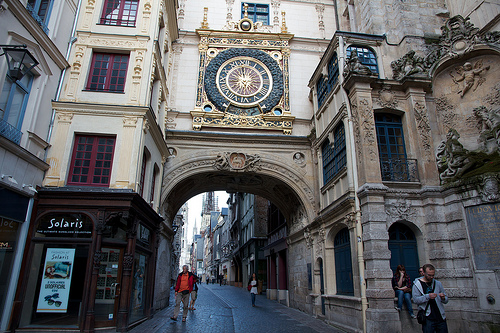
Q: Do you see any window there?
A: Yes, there is a window.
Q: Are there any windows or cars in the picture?
A: Yes, there is a window.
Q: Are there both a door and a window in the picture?
A: Yes, there are both a window and a door.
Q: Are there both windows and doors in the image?
A: Yes, there are both a window and a door.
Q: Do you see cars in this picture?
A: No, there are no cars.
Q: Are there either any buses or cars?
A: No, there are no cars or buses.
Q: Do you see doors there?
A: Yes, there is a door.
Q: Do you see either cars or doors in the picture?
A: Yes, there is a door.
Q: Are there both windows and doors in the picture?
A: Yes, there are both a door and a window.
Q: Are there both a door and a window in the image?
A: Yes, there are both a door and a window.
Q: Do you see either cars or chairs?
A: No, there are no cars or chairs.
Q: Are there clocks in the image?
A: Yes, there is a clock.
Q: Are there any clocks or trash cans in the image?
A: Yes, there is a clock.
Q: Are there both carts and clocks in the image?
A: No, there is a clock but no carts.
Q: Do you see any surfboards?
A: No, there are no surfboards.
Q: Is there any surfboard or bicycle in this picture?
A: No, there are no surfboards or bicycles.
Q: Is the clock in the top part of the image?
A: Yes, the clock is in the top of the image.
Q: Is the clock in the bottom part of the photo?
A: No, the clock is in the top of the image.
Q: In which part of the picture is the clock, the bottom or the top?
A: The clock is in the top of the image.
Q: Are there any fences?
A: No, there are no fences.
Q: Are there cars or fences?
A: No, there are no fences or cars.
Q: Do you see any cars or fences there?
A: No, there are no fences or cars.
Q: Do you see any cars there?
A: No, there are no cars.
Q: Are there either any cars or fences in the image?
A: No, there are no cars or fences.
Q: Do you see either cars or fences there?
A: No, there are no cars or fences.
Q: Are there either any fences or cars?
A: No, there are no cars or fences.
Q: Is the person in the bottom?
A: Yes, the person is in the bottom of the image.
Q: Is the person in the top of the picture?
A: No, the person is in the bottom of the image.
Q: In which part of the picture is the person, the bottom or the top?
A: The person is in the bottom of the image.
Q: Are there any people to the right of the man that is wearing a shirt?
A: Yes, there is a person to the right of the man.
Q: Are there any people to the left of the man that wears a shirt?
A: No, the person is to the right of the man.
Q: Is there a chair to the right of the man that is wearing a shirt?
A: No, there is a person to the right of the man.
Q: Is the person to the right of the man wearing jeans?
A: Yes, the person is wearing jeans.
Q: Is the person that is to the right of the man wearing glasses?
A: No, the person is wearing jeans.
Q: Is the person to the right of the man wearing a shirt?
A: Yes, the person is wearing a shirt.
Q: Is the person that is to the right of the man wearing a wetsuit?
A: No, the person is wearing a shirt.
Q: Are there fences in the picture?
A: No, there are no fences.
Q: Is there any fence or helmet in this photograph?
A: No, there are no fences or helmets.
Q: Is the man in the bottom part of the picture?
A: Yes, the man is in the bottom of the image.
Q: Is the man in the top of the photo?
A: No, the man is in the bottom of the image.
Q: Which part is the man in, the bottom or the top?
A: The man is in the bottom of the image.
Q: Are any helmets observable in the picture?
A: No, there are no helmets.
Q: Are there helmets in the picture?
A: No, there are no helmets.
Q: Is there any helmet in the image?
A: No, there are no helmets.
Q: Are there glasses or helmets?
A: No, there are no helmets or glasses.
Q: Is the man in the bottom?
A: Yes, the man is in the bottom of the image.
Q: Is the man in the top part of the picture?
A: No, the man is in the bottom of the image.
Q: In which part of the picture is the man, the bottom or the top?
A: The man is in the bottom of the image.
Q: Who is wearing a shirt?
A: The man is wearing a shirt.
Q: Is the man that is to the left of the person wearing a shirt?
A: Yes, the man is wearing a shirt.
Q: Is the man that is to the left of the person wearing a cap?
A: No, the man is wearing a shirt.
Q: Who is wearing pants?
A: The man is wearing pants.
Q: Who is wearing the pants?
A: The man is wearing pants.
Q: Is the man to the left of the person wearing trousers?
A: Yes, the man is wearing trousers.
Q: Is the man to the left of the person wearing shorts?
A: No, the man is wearing trousers.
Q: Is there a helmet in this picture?
A: No, there are no helmets.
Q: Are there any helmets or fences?
A: No, there are no helmets or fences.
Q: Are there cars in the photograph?
A: No, there are no cars.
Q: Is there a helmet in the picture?
A: No, there are no helmets.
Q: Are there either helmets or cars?
A: No, there are no helmets or cars.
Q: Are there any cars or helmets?
A: No, there are no helmets or cars.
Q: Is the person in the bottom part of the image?
A: Yes, the person is in the bottom of the image.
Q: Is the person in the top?
A: No, the person is in the bottom of the image.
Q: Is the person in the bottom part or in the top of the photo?
A: The person is in the bottom of the image.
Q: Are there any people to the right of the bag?
A: No, the person is to the left of the bag.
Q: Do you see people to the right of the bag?
A: No, the person is to the left of the bag.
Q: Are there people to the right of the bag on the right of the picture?
A: No, the person is to the left of the bag.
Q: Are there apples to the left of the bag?
A: No, there is a person to the left of the bag.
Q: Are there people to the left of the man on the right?
A: Yes, there is a person to the left of the man.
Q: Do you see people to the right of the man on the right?
A: No, the person is to the left of the man.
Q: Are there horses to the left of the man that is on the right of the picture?
A: No, there is a person to the left of the man.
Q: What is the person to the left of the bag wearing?
A: The person is wearing jeans.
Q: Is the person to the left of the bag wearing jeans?
A: Yes, the person is wearing jeans.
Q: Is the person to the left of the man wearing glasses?
A: No, the person is wearing jeans.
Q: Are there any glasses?
A: No, there are no glasses.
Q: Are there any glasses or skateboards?
A: No, there are no glasses or skateboards.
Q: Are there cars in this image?
A: No, there are no cars.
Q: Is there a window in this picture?
A: Yes, there is a window.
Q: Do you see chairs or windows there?
A: Yes, there is a window.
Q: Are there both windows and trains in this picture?
A: No, there is a window but no trains.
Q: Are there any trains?
A: No, there are no trains.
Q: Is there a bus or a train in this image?
A: No, there are no trains or buses.